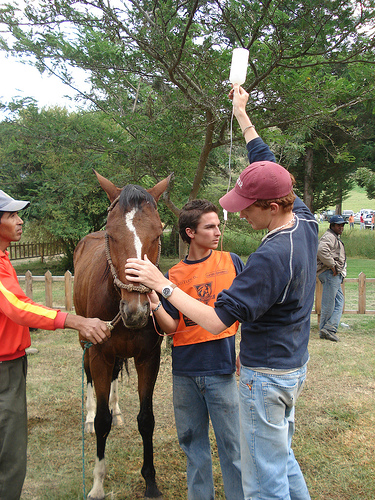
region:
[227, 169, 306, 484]
this is a man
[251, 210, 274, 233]
the man is light skinned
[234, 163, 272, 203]
this is a cap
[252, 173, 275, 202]
the cap is red in color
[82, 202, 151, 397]
this is a horse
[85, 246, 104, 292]
the horse is brown in color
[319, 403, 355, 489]
this is a grass area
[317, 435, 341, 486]
the grass is green in color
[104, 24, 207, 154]
this is a tree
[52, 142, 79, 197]
the leaves are green in color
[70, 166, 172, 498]
Brownish horse with white stripe on the head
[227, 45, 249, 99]
White bottle held by the hand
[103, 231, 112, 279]
A rope on the side of the horse's head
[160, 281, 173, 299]
A black faced wrist watch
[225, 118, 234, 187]
A white drip line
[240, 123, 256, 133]
A metallic bracelet on the wrist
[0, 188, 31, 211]
A grey cap on the head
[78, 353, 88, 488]
A blue string hanging from the horse's side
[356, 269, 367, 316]
Part of a wooden fence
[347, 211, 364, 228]
Two people in the background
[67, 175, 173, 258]
a brown horse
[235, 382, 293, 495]
man is wearing light blue jeans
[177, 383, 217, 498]
blue jean pants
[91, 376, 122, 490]
the horses leg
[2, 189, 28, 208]
man wearing a grey hat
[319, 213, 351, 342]
a person standing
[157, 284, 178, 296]
man wearing a watch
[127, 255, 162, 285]
the man touching the horse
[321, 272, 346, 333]
man wearing blue jeans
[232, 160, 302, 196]
a red hat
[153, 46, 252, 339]
A small white bottle with a tube attached.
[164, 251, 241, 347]
A bright orange vest.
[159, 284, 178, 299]
A wrist watch.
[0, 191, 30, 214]
A grey colored hat.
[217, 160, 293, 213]
A maroon ball cap.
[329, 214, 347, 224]
A blue ball cap.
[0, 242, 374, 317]
A brown wooden fence.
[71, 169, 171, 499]
A brown horse with white markings.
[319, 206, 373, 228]
Vehicles parked.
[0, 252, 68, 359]
A long sleeved red top with a yellow strip down the arm of it.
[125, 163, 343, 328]
a man touching a horse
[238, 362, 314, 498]
a man wearing blue jeans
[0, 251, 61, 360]
man wearing a red windbreaker with yellow lines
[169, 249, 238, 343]
man wearing an orange security vest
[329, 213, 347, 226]
man wearing a blue cap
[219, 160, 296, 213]
man with red hair wearing a red cap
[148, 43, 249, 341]
man holding an IV bottle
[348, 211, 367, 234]
two people standing in the grass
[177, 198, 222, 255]
man with short brown hair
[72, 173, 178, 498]
a brown horse with white and black legs